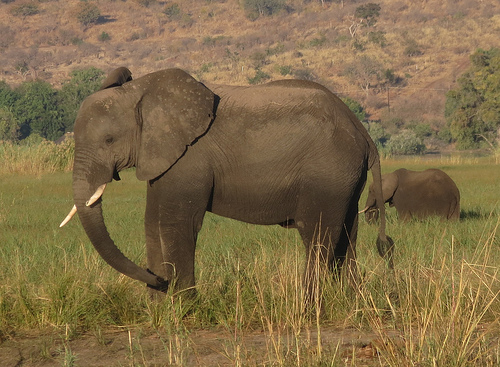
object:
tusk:
[85, 183, 107, 206]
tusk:
[53, 207, 76, 226]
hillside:
[0, 2, 498, 147]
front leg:
[153, 204, 208, 321]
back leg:
[298, 204, 340, 284]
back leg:
[330, 189, 359, 279]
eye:
[101, 130, 116, 147]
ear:
[117, 65, 215, 182]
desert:
[0, 0, 500, 140]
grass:
[0, 141, 500, 366]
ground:
[0, 158, 500, 367]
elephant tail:
[366, 147, 397, 268]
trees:
[18, 70, 102, 138]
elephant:
[358, 166, 460, 224]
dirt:
[156, 314, 351, 355]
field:
[0, 156, 500, 367]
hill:
[0, 0, 500, 151]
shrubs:
[453, 88, 488, 136]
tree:
[425, 38, 498, 171]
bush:
[0, 126, 75, 176]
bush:
[365, 118, 430, 161]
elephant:
[56, 64, 396, 319]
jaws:
[66, 153, 132, 181]